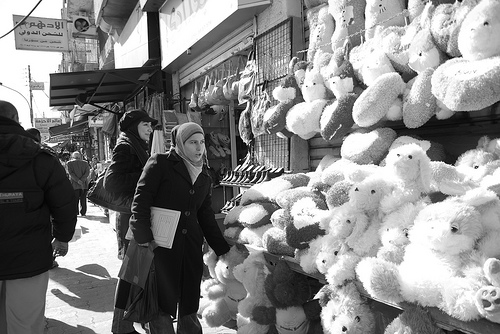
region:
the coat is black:
[134, 159, 209, 305]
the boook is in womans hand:
[126, 200, 186, 254]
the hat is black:
[114, 102, 156, 129]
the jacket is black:
[8, 129, 68, 288]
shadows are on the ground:
[60, 260, 103, 308]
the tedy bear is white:
[356, 212, 498, 300]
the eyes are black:
[352, 312, 364, 322]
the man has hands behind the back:
[66, 148, 96, 225]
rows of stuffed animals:
[220, 4, 499, 333]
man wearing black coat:
[2, 103, 79, 333]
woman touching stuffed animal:
[115, 124, 241, 333]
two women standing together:
[87, 110, 239, 332]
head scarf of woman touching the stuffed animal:
[168, 118, 205, 178]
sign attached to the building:
[11, 14, 104, 61]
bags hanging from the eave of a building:
[182, 56, 250, 113]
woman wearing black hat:
[109, 102, 157, 259]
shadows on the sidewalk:
[45, 217, 130, 332]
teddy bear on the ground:
[312, 284, 368, 332]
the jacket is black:
[140, 156, 229, 308]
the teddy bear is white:
[395, 202, 490, 329]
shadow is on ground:
[59, 259, 114, 303]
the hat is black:
[119, 110, 154, 126]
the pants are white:
[10, 281, 55, 332]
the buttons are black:
[183, 182, 195, 237]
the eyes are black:
[370, 185, 377, 193]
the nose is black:
[353, 186, 355, 193]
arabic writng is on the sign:
[21, 17, 68, 45]